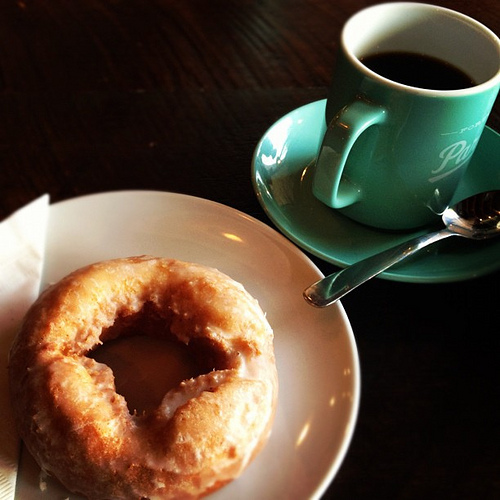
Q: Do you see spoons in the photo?
A: Yes, there is a spoon.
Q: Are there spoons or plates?
A: Yes, there is a spoon.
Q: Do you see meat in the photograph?
A: No, there is no meat.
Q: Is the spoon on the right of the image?
A: Yes, the spoon is on the right of the image.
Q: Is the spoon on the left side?
A: No, the spoon is on the right of the image.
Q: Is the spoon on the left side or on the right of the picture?
A: The spoon is on the right of the image.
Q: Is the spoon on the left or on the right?
A: The spoon is on the right of the image.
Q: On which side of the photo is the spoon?
A: The spoon is on the right of the image.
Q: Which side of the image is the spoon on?
A: The spoon is on the right of the image.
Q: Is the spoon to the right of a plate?
A: Yes, the spoon is to the right of a plate.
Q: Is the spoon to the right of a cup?
A: No, the spoon is to the right of a plate.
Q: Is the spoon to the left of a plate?
A: No, the spoon is to the right of a plate.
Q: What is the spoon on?
A: The spoon is on the plate.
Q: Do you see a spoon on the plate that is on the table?
A: Yes, there is a spoon on the plate.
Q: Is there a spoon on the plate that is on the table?
A: Yes, there is a spoon on the plate.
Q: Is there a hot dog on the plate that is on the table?
A: No, there is a spoon on the plate.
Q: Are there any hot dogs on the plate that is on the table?
A: No, there is a spoon on the plate.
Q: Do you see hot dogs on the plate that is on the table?
A: No, there is a spoon on the plate.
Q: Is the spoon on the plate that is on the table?
A: Yes, the spoon is on the plate.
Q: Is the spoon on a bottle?
A: No, the spoon is on the plate.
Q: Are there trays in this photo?
A: No, there are no trays.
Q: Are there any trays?
A: No, there are no trays.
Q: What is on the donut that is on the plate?
A: The glaze is on the donut.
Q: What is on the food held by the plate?
A: The glaze is on the donut.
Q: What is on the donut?
A: The glaze is on the donut.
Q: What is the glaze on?
A: The glaze is on the donut.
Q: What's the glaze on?
A: The glaze is on the donut.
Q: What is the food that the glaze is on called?
A: The food is a donut.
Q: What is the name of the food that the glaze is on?
A: The food is a donut.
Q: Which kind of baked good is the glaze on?
A: The glaze is on the doughnut.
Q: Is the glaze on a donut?
A: Yes, the glaze is on a donut.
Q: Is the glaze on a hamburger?
A: No, the glaze is on a donut.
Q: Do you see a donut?
A: Yes, there is a donut.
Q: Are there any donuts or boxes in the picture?
A: Yes, there is a donut.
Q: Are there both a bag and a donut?
A: No, there is a donut but no bags.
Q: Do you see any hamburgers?
A: No, there are no hamburgers.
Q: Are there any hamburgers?
A: No, there are no hamburgers.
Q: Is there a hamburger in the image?
A: No, there are no hamburgers.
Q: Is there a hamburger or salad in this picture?
A: No, there are no hamburgers or salad.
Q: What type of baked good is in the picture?
A: The baked good is a donut.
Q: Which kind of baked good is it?
A: The food is a donut.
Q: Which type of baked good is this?
A: This is a donut.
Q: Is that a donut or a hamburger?
A: That is a donut.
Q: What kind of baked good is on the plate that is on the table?
A: The food is a donut.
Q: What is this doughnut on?
A: The doughnut is on the plate.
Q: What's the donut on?
A: The doughnut is on the plate.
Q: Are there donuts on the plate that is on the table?
A: Yes, there is a donut on the plate.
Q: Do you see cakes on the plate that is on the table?
A: No, there is a donut on the plate.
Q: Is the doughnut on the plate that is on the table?
A: Yes, the doughnut is on the plate.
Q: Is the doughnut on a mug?
A: No, the doughnut is on the plate.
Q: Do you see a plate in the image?
A: Yes, there is a plate.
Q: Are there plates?
A: Yes, there is a plate.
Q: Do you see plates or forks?
A: Yes, there is a plate.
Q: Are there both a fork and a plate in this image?
A: No, there is a plate but no forks.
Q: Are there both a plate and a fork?
A: No, there is a plate but no forks.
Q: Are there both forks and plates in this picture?
A: No, there is a plate but no forks.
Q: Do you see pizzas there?
A: No, there are no pizzas.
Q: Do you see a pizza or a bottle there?
A: No, there are no pizzas or bottles.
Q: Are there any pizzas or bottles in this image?
A: No, there are no pizzas or bottles.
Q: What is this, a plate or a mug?
A: This is a plate.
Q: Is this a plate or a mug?
A: This is a plate.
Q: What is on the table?
A: The plate is on the table.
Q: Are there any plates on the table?
A: Yes, there is a plate on the table.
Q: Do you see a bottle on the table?
A: No, there is a plate on the table.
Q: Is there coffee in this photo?
A: Yes, there is coffee.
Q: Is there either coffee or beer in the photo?
A: Yes, there is coffee.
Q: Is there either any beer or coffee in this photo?
A: Yes, there is coffee.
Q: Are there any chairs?
A: No, there are no chairs.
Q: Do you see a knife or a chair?
A: No, there are no chairs or knives.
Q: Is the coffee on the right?
A: Yes, the coffee is on the right of the image.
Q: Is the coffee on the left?
A: No, the coffee is on the right of the image.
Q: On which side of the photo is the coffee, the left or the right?
A: The coffee is on the right of the image.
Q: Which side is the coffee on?
A: The coffee is on the right of the image.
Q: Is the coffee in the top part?
A: Yes, the coffee is in the top of the image.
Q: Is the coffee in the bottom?
A: No, the coffee is in the top of the image.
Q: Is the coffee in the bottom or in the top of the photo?
A: The coffee is in the top of the image.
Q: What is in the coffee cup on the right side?
A: The coffee is in the coffee cup.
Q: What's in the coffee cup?
A: The coffee is in the coffee cup.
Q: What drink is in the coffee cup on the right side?
A: The drink is coffee.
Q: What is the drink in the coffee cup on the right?
A: The drink is coffee.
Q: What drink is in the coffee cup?
A: The drink is coffee.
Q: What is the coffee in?
A: The coffee is in the coffee cup.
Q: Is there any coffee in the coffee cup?
A: Yes, there is coffee in the coffee cup.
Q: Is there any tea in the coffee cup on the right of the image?
A: No, there is coffee in the coffee cup.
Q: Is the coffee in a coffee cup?
A: Yes, the coffee is in a coffee cup.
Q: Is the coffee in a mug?
A: No, the coffee is in a coffee cup.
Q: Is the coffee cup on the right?
A: Yes, the coffee cup is on the right of the image.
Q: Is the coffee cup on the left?
A: No, the coffee cup is on the right of the image.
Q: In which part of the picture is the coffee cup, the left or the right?
A: The coffee cup is on the right of the image.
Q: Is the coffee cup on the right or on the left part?
A: The coffee cup is on the right of the image.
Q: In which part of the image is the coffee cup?
A: The coffee cup is on the right of the image.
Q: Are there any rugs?
A: No, there are no rugs.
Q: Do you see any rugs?
A: No, there are no rugs.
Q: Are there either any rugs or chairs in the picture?
A: No, there are no rugs or chairs.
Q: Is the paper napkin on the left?
A: Yes, the napkin is on the left of the image.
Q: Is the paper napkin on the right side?
A: No, the napkin is on the left of the image.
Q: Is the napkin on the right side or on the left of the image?
A: The napkin is on the left of the image.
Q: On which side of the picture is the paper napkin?
A: The napkin is on the left of the image.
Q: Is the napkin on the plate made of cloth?
A: No, the napkin is made of paper.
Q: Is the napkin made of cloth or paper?
A: The napkin is made of paper.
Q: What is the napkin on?
A: The napkin is on the plate.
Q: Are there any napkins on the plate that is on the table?
A: Yes, there is a napkin on the plate.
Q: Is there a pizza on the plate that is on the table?
A: No, there is a napkin on the plate.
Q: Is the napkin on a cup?
A: No, the napkin is on the plate.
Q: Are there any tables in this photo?
A: Yes, there is a table.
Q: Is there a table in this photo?
A: Yes, there is a table.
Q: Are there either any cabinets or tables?
A: Yes, there is a table.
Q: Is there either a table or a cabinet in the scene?
A: Yes, there is a table.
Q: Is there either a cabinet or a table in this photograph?
A: Yes, there is a table.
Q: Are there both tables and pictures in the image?
A: No, there is a table but no pictures.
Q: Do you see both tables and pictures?
A: No, there is a table but no pictures.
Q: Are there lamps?
A: No, there are no lamps.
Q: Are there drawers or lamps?
A: No, there are no lamps or drawers.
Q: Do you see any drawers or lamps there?
A: No, there are no lamps or drawers.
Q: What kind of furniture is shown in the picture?
A: The furniture is a table.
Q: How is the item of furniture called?
A: The piece of furniture is a table.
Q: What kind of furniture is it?
A: The piece of furniture is a table.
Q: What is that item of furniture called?
A: This is a table.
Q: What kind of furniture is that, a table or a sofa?
A: This is a table.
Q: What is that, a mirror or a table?
A: That is a table.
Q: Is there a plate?
A: Yes, there is a plate.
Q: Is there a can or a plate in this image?
A: Yes, there is a plate.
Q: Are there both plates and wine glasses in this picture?
A: No, there is a plate but no wine glasses.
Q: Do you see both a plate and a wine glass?
A: No, there is a plate but no wine glasses.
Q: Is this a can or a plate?
A: This is a plate.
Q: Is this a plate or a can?
A: This is a plate.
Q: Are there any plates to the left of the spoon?
A: Yes, there is a plate to the left of the spoon.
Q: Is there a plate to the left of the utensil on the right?
A: Yes, there is a plate to the left of the spoon.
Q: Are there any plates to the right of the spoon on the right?
A: No, the plate is to the left of the spoon.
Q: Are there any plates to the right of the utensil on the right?
A: No, the plate is to the left of the spoon.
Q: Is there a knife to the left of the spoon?
A: No, there is a plate to the left of the spoon.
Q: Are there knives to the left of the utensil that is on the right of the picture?
A: No, there is a plate to the left of the spoon.